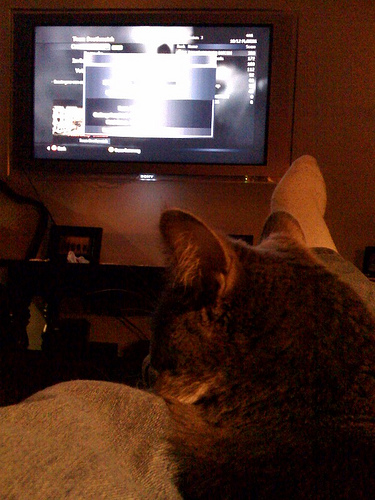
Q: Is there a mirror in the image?
A: No, there are no mirrors.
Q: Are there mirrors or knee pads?
A: No, there are no mirrors or knee pads.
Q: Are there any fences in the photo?
A: No, there are no fences.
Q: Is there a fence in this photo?
A: No, there are no fences.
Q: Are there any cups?
A: No, there are no cups.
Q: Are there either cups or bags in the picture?
A: No, there are no cups or bags.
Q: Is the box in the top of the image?
A: Yes, the box is in the top of the image.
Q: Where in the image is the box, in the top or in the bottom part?
A: The box is in the top of the image.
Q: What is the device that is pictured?
A: The device is a screen.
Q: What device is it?
A: The device is a screen.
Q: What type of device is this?
A: That is a screen.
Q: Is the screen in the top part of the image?
A: Yes, the screen is in the top of the image.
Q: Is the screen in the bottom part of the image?
A: No, the screen is in the top of the image.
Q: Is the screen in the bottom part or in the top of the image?
A: The screen is in the top of the image.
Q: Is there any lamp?
A: No, there are no lamps.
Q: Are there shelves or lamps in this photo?
A: No, there are no lamps or shelves.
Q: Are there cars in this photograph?
A: No, there are no cars.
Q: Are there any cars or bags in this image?
A: No, there are no cars or bags.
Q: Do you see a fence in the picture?
A: No, there are no fences.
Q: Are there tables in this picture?
A: Yes, there is a table.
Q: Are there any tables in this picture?
A: Yes, there is a table.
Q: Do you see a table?
A: Yes, there is a table.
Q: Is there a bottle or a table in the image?
A: Yes, there is a table.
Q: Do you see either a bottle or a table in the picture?
A: Yes, there is a table.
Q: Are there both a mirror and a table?
A: No, there is a table but no mirrors.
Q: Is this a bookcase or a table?
A: This is a table.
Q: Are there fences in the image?
A: No, there are no fences.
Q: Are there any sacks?
A: No, there are no sacks.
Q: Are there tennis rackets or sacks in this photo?
A: No, there are no sacks or tennis rackets.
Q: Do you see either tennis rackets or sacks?
A: No, there are no sacks or tennis rackets.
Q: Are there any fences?
A: No, there are no fences.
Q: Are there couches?
A: Yes, there is a couch.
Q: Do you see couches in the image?
A: Yes, there is a couch.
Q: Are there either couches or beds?
A: Yes, there is a couch.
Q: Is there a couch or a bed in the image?
A: Yes, there is a couch.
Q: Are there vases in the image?
A: No, there are no vases.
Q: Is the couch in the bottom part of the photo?
A: Yes, the couch is in the bottom of the image.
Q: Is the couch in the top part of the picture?
A: No, the couch is in the bottom of the image.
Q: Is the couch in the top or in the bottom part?
A: The couch is in the bottom of the image.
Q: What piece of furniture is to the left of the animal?
A: The piece of furniture is a couch.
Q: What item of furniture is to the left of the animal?
A: The piece of furniture is a couch.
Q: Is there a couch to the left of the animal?
A: Yes, there is a couch to the left of the animal.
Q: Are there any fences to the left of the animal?
A: No, there is a couch to the left of the animal.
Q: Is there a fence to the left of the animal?
A: No, there is a couch to the left of the animal.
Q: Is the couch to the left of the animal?
A: Yes, the couch is to the left of the animal.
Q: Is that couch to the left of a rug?
A: No, the couch is to the left of the animal.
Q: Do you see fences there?
A: No, there are no fences.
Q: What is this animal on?
A: The animal is on the couch.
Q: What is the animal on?
A: The animal is on the couch.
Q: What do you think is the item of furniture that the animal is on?
A: The piece of furniture is a couch.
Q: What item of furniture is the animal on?
A: The animal is on the couch.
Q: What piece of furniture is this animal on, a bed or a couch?
A: The animal is on a couch.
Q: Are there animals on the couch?
A: Yes, there is an animal on the couch.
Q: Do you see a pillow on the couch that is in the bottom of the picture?
A: No, there is an animal on the couch.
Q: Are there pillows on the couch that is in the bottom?
A: No, there is an animal on the couch.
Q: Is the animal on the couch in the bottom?
A: Yes, the animal is on the couch.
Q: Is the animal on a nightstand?
A: No, the animal is on the couch.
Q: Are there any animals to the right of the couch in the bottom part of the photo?
A: Yes, there is an animal to the right of the couch.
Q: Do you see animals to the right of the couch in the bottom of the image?
A: Yes, there is an animal to the right of the couch.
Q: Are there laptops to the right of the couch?
A: No, there is an animal to the right of the couch.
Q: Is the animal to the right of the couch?
A: Yes, the animal is to the right of the couch.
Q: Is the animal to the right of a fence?
A: No, the animal is to the right of the couch.